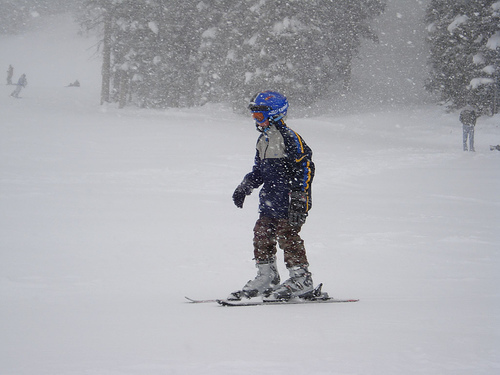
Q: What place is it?
A: It is a field.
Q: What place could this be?
A: It is a field.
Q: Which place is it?
A: It is a field.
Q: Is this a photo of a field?
A: Yes, it is showing a field.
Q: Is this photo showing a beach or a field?
A: It is showing a field.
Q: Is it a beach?
A: No, it is a field.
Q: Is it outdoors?
A: Yes, it is outdoors.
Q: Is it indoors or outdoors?
A: It is outdoors.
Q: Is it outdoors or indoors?
A: It is outdoors.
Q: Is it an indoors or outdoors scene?
A: It is outdoors.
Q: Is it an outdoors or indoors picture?
A: It is outdoors.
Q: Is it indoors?
A: No, it is outdoors.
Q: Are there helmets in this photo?
A: Yes, there is a helmet.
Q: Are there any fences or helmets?
A: Yes, there is a helmet.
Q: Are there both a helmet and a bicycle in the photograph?
A: No, there is a helmet but no bicycles.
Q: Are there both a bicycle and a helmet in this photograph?
A: No, there is a helmet but no bicycles.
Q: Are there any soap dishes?
A: No, there are no soap dishes.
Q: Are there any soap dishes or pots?
A: No, there are no soap dishes or pots.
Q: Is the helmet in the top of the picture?
A: Yes, the helmet is in the top of the image.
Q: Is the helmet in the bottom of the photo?
A: No, the helmet is in the top of the image.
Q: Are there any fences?
A: No, there are no fences.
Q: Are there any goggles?
A: Yes, there are goggles.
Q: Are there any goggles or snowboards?
A: Yes, there are goggles.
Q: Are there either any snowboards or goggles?
A: Yes, there are goggles.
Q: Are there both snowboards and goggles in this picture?
A: No, there are goggles but no snowboards.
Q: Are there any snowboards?
A: No, there are no snowboards.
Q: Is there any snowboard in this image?
A: No, there are no snowboards.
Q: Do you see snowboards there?
A: No, there are no snowboards.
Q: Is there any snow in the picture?
A: Yes, there is snow.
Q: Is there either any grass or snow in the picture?
A: Yes, there is snow.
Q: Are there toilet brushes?
A: No, there are no toilet brushes.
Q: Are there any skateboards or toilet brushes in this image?
A: No, there are no toilet brushes or skateboards.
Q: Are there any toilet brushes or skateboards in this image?
A: No, there are no toilet brushes or skateboards.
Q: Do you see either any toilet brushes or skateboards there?
A: No, there are no toilet brushes or skateboards.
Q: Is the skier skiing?
A: Yes, the skier is skiing.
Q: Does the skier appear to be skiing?
A: Yes, the skier is skiing.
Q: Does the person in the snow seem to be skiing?
A: Yes, the skier is skiing.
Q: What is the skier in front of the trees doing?
A: The skier is skiing.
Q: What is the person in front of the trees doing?
A: The skier is skiing.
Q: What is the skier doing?
A: The skier is skiing.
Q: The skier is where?
A: The skier is in the snow.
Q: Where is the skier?
A: The skier is in the snow.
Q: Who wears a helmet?
A: The skier wears a helmet.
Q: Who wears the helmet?
A: The skier wears a helmet.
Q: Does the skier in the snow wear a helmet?
A: Yes, the skier wears a helmet.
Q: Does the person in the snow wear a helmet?
A: Yes, the skier wears a helmet.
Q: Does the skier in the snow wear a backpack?
A: No, the skier wears a helmet.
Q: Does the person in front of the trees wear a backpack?
A: No, the skier wears a helmet.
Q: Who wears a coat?
A: The skier wears a coat.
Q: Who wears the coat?
A: The skier wears a coat.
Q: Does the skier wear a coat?
A: Yes, the skier wears a coat.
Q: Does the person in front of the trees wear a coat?
A: Yes, the skier wears a coat.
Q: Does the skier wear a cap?
A: No, the skier wears a coat.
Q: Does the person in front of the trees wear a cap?
A: No, the skier wears a coat.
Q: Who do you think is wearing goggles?
A: The skier is wearing goggles.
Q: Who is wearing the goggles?
A: The skier is wearing goggles.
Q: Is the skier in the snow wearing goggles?
A: Yes, the skier is wearing goggles.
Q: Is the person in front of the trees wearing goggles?
A: Yes, the skier is wearing goggles.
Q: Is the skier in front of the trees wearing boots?
A: No, the skier is wearing goggles.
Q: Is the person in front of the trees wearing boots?
A: No, the skier is wearing goggles.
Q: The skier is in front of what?
A: The skier is in front of the trees.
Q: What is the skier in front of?
A: The skier is in front of the trees.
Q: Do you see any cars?
A: No, there are no cars.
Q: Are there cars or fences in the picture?
A: No, there are no cars or fences.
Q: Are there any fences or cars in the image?
A: No, there are no cars or fences.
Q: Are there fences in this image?
A: No, there are no fences.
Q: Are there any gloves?
A: Yes, there are gloves.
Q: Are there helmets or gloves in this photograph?
A: Yes, there are gloves.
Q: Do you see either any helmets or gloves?
A: Yes, there are gloves.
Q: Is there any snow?
A: Yes, there is snow.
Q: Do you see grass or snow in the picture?
A: Yes, there is snow.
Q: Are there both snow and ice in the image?
A: No, there is snow but no ice.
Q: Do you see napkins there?
A: No, there are no napkins.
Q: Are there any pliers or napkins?
A: No, there are no napkins or pliers.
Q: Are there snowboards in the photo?
A: No, there are no snowboards.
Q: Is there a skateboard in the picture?
A: No, there are no skateboards.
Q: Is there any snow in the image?
A: Yes, there is snow.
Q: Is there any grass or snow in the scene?
A: Yes, there is snow.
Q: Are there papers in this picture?
A: No, there are no papers.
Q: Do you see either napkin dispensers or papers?
A: No, there are no papers or napkin dispensers.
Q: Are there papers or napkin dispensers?
A: No, there are no papers or napkin dispensers.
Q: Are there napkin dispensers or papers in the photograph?
A: No, there are no papers or napkin dispensers.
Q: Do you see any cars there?
A: No, there are no cars.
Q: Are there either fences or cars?
A: No, there are no cars or fences.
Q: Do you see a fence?
A: No, there are no fences.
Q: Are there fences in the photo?
A: No, there are no fences.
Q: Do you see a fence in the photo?
A: No, there are no fences.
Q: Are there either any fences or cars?
A: No, there are no fences or cars.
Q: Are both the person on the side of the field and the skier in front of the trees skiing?
A: Yes, both the person and the skier are skiing.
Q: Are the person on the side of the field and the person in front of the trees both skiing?
A: Yes, both the person and the skier are skiing.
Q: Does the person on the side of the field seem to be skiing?
A: Yes, the person is skiing.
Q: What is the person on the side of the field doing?
A: The person is skiing.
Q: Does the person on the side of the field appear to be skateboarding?
A: No, the person is skiing.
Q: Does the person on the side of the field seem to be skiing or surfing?
A: The person is skiing.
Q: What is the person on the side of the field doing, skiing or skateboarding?
A: The person is skiing.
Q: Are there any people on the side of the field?
A: Yes, there is a person on the side of the field.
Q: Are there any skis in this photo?
A: Yes, there are skis.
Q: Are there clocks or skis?
A: Yes, there are skis.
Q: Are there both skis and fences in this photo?
A: No, there are skis but no fences.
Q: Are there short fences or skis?
A: Yes, there are short skis.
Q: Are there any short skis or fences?
A: Yes, there are short skis.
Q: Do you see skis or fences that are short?
A: Yes, the skis are short.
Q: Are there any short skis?
A: Yes, there are short skis.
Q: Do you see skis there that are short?
A: Yes, there are skis that are short.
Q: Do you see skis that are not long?
A: Yes, there are short skis.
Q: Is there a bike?
A: No, there are no bikes.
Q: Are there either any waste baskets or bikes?
A: No, there are no bikes or waste baskets.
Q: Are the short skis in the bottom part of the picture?
A: Yes, the skis are in the bottom of the image.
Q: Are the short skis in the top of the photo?
A: No, the skis are in the bottom of the image.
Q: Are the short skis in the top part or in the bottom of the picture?
A: The skis are in the bottom of the image.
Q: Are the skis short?
A: Yes, the skis are short.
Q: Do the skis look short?
A: Yes, the skis are short.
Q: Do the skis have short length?
A: Yes, the skis are short.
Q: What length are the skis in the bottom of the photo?
A: The skis are short.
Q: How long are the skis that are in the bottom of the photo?
A: The skis are short.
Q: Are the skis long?
A: No, the skis are short.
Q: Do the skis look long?
A: No, the skis are short.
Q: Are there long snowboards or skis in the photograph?
A: No, there are skis but they are short.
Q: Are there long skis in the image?
A: No, there are skis but they are short.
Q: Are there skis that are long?
A: No, there are skis but they are short.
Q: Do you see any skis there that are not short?
A: No, there are skis but they are short.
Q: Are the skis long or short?
A: The skis are short.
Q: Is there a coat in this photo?
A: Yes, there is a coat.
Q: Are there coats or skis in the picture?
A: Yes, there is a coat.